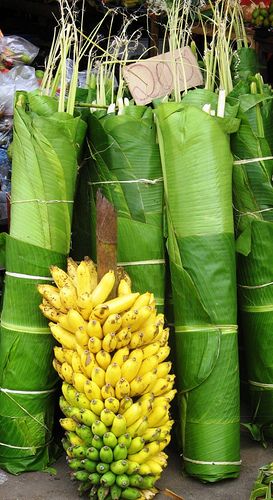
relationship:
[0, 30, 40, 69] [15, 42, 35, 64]
plastic with lime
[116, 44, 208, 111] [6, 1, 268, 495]
sign with price of banana leaves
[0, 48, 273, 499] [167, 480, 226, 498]
banana leaf laying on ground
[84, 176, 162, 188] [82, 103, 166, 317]
string keeping banana leaves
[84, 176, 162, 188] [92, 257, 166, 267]
string keeping string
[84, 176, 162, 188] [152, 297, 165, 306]
string keeping string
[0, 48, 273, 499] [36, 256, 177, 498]
banana leaf with banana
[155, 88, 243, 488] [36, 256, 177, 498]
banana leaf with banana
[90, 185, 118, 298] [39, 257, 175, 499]
stem of banana bunches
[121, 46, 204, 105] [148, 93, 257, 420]
price card kept in leaf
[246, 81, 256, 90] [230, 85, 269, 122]
stem in leaf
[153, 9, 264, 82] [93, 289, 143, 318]
table near banana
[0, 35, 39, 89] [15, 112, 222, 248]
covers near banana leaves